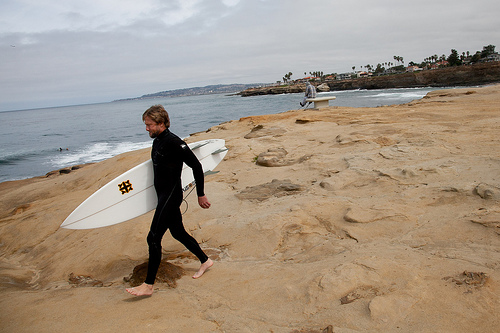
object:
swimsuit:
[144, 127, 209, 286]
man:
[124, 104, 217, 299]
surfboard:
[58, 137, 227, 230]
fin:
[191, 141, 210, 150]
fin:
[210, 147, 230, 155]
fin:
[205, 169, 220, 175]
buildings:
[296, 54, 499, 83]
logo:
[117, 180, 134, 195]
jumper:
[299, 80, 316, 107]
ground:
[1, 82, 498, 331]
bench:
[306, 96, 339, 109]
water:
[0, 85, 476, 184]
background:
[0, 0, 499, 183]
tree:
[281, 72, 291, 86]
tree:
[350, 65, 358, 72]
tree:
[392, 55, 397, 67]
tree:
[432, 55, 440, 61]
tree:
[466, 49, 470, 56]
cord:
[179, 181, 199, 215]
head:
[140, 105, 173, 138]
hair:
[141, 105, 172, 128]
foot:
[126, 282, 155, 296]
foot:
[192, 258, 214, 279]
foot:
[300, 102, 304, 107]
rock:
[58, 167, 70, 175]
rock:
[71, 165, 81, 170]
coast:
[0, 86, 480, 185]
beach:
[0, 81, 493, 326]